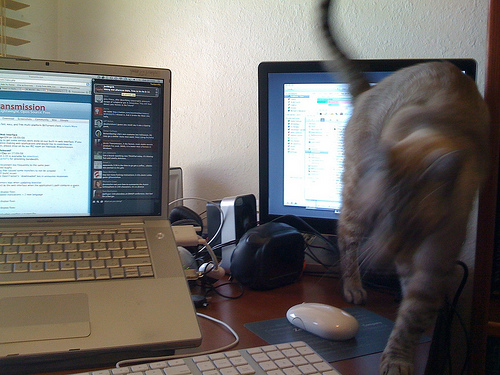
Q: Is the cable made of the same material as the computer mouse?
A: Yes, both the cable and the computer mouse are made of plastic.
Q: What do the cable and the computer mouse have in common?
A: The material, both the cable and the computer mouse are plastic.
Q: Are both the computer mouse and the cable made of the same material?
A: Yes, both the computer mouse and the cable are made of plastic.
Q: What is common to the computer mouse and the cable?
A: The material, both the computer mouse and the cable are plastic.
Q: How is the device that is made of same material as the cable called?
A: The device is a computer mouse.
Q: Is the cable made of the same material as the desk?
A: No, the cable is made of plastic and the desk is made of wood.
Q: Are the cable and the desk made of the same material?
A: No, the cable is made of plastic and the desk is made of wood.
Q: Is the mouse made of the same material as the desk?
A: No, the mouse is made of plastic and the desk is made of wood.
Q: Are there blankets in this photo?
A: No, there are no blankets.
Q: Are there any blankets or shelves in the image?
A: No, there are no blankets or shelves.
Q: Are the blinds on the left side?
A: Yes, the blinds are on the left of the image.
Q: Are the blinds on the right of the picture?
A: No, the blinds are on the left of the image.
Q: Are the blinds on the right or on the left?
A: The blinds are on the left of the image.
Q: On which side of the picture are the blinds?
A: The blinds are on the left of the image.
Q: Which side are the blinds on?
A: The blinds are on the left of the image.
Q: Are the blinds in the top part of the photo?
A: Yes, the blinds are in the top of the image.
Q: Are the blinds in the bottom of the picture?
A: No, the blinds are in the top of the image.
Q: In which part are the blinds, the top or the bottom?
A: The blinds are in the top of the image.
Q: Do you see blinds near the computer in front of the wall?
A: Yes, there are blinds near the computer.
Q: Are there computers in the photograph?
A: Yes, there is a computer.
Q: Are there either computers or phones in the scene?
A: Yes, there is a computer.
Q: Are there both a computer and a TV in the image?
A: No, there is a computer but no televisions.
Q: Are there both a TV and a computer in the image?
A: No, there is a computer but no televisions.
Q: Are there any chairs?
A: No, there are no chairs.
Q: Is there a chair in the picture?
A: No, there are no chairs.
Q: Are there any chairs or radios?
A: No, there are no chairs or radios.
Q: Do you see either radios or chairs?
A: No, there are no chairs or radios.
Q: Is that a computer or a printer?
A: That is a computer.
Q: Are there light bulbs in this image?
A: No, there are no light bulbs.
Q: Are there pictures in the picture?
A: No, there are no pictures.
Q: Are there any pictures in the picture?
A: No, there are no pictures.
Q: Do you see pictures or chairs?
A: No, there are no pictures or chairs.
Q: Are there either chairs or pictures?
A: No, there are no pictures or chairs.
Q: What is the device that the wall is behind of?
A: The device is a computer.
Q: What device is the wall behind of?
A: The wall is behind the computer.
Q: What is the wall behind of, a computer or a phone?
A: The wall is behind a computer.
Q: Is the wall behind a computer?
A: Yes, the wall is behind a computer.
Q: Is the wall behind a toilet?
A: No, the wall is behind a computer.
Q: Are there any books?
A: No, there are no books.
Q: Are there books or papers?
A: No, there are no books or papers.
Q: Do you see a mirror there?
A: No, there are no mirrors.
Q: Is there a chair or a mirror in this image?
A: No, there are no mirrors or chairs.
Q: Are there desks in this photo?
A: Yes, there is a desk.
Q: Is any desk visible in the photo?
A: Yes, there is a desk.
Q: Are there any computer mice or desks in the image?
A: Yes, there is a desk.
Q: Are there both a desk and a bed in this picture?
A: No, there is a desk but no beds.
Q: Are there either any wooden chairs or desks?
A: Yes, there is a wood desk.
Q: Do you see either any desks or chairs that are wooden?
A: Yes, the desk is wooden.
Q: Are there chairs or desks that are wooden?
A: Yes, the desk is wooden.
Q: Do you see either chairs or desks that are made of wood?
A: Yes, the desk is made of wood.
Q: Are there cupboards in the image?
A: No, there are no cupboards.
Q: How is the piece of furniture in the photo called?
A: The piece of furniture is a desk.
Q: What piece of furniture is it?
A: The piece of furniture is a desk.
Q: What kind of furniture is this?
A: This is a desk.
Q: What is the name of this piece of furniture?
A: This is a desk.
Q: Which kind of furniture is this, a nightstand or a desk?
A: This is a desk.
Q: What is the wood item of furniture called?
A: The piece of furniture is a desk.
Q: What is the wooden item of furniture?
A: The piece of furniture is a desk.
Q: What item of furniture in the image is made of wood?
A: The piece of furniture is a desk.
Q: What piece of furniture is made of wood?
A: The piece of furniture is a desk.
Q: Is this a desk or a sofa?
A: This is a desk.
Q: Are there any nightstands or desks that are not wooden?
A: No, there is a desk but it is wooden.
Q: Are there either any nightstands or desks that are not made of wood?
A: No, there is a desk but it is made of wood.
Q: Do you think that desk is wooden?
A: Yes, the desk is wooden.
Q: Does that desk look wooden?
A: Yes, the desk is wooden.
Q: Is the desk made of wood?
A: Yes, the desk is made of wood.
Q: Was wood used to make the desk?
A: Yes, the desk is made of wood.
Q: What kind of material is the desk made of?
A: The desk is made of wood.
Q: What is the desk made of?
A: The desk is made of wood.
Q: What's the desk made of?
A: The desk is made of wood.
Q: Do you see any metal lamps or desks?
A: No, there is a desk but it is wooden.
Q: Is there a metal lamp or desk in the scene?
A: No, there is a desk but it is wooden.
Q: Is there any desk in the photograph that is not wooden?
A: No, there is a desk but it is wooden.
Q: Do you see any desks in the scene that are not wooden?
A: No, there is a desk but it is wooden.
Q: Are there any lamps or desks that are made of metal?
A: No, there is a desk but it is made of wood.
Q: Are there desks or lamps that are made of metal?
A: No, there is a desk but it is made of wood.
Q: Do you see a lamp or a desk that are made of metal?
A: No, there is a desk but it is made of wood.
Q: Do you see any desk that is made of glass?
A: No, there is a desk but it is made of wood.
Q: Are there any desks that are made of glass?
A: No, there is a desk but it is made of wood.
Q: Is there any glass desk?
A: No, there is a desk but it is made of wood.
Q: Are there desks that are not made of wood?
A: No, there is a desk but it is made of wood.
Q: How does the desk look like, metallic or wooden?
A: The desk is wooden.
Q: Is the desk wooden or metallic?
A: The desk is wooden.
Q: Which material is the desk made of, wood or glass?
A: The desk is made of wood.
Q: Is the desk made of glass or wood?
A: The desk is made of wood.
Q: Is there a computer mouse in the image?
A: Yes, there is a computer mouse.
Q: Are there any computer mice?
A: Yes, there is a computer mouse.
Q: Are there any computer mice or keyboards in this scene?
A: Yes, there is a computer mouse.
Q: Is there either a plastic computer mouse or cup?
A: Yes, there is a plastic computer mouse.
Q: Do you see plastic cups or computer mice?
A: Yes, there is a plastic computer mouse.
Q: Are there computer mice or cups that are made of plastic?
A: Yes, the computer mouse is made of plastic.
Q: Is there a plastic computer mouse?
A: Yes, there is a computer mouse that is made of plastic.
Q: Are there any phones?
A: No, there are no phones.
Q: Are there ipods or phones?
A: No, there are no phones or ipods.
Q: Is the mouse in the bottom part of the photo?
A: Yes, the mouse is in the bottom of the image.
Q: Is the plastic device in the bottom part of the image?
A: Yes, the mouse is in the bottom of the image.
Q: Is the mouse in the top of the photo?
A: No, the mouse is in the bottom of the image.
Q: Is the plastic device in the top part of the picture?
A: No, the mouse is in the bottom of the image.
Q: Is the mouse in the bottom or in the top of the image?
A: The mouse is in the bottom of the image.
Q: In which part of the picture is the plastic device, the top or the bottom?
A: The mouse is in the bottom of the image.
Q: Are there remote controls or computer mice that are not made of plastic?
A: No, there is a computer mouse but it is made of plastic.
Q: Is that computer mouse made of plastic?
A: Yes, the computer mouse is made of plastic.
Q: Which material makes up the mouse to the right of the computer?
A: The mouse is made of plastic.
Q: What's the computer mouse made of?
A: The mouse is made of plastic.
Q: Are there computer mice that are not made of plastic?
A: No, there is a computer mouse but it is made of plastic.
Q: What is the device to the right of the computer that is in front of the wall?
A: The device is a computer mouse.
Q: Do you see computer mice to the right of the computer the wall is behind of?
A: Yes, there is a computer mouse to the right of the computer.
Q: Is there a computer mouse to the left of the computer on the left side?
A: No, the computer mouse is to the right of the computer.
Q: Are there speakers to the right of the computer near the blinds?
A: No, there is a computer mouse to the right of the computer.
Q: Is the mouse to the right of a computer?
A: Yes, the mouse is to the right of a computer.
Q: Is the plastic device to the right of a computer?
A: Yes, the mouse is to the right of a computer.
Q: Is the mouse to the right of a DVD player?
A: No, the mouse is to the right of a computer.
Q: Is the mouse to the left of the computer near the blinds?
A: No, the mouse is to the right of the computer.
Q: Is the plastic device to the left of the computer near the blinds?
A: No, the mouse is to the right of the computer.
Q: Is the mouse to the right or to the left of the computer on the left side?
A: The mouse is to the right of the computer.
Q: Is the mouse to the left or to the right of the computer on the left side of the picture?
A: The mouse is to the right of the computer.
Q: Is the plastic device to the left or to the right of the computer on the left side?
A: The mouse is to the right of the computer.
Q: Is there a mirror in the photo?
A: No, there are no mirrors.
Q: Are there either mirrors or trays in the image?
A: No, there are no mirrors or trays.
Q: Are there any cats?
A: Yes, there is a cat.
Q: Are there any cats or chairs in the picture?
A: Yes, there is a cat.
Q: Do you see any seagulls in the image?
A: No, there are no seagulls.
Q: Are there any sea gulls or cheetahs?
A: No, there are no sea gulls or cheetahs.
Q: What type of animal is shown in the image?
A: The animal is a cat.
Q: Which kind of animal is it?
A: The animal is a cat.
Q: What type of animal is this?
A: This is a cat.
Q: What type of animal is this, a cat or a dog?
A: This is a cat.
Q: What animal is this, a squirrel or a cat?
A: This is a cat.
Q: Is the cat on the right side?
A: Yes, the cat is on the right of the image.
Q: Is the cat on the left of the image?
A: No, the cat is on the right of the image.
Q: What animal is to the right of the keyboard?
A: The animal is a cat.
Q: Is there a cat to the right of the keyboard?
A: Yes, there is a cat to the right of the keyboard.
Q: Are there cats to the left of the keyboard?
A: No, the cat is to the right of the keyboard.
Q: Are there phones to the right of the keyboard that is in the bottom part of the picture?
A: No, there is a cat to the right of the keyboard.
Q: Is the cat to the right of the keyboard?
A: Yes, the cat is to the right of the keyboard.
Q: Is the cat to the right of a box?
A: No, the cat is to the right of the keyboard.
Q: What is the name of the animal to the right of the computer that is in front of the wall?
A: The animal is a cat.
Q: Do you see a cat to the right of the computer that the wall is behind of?
A: Yes, there is a cat to the right of the computer.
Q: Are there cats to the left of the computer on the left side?
A: No, the cat is to the right of the computer.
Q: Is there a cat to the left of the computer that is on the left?
A: No, the cat is to the right of the computer.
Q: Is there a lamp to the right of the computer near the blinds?
A: No, there is a cat to the right of the computer.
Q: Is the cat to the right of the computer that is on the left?
A: Yes, the cat is to the right of the computer.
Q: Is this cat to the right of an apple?
A: No, the cat is to the right of the computer.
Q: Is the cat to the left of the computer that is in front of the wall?
A: No, the cat is to the right of the computer.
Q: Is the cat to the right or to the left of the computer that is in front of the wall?
A: The cat is to the right of the computer.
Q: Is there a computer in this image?
A: Yes, there is a computer.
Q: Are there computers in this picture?
A: Yes, there is a computer.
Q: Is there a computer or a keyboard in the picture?
A: Yes, there is a computer.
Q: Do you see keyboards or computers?
A: Yes, there is a computer.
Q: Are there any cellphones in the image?
A: No, there are no cellphones.